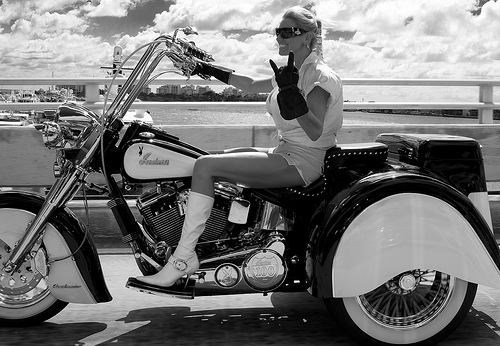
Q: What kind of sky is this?
A: Cloudy sky.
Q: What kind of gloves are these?
A: Black gloves.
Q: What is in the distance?
A: A body of water.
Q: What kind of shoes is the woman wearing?
A: Boots.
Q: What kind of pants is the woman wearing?
A: Shorts.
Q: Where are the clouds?
A: In sky.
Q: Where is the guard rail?
A: Behind bike.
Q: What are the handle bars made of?
A: Chrome.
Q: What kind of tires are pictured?
A: White wall.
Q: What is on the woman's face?
A: Sun Glasses.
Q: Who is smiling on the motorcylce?
A: A girl with a white shirt and boots.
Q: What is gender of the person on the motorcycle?
A: A female.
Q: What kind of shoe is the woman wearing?
A: White knee high boots.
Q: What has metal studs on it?
A: The black leather seat.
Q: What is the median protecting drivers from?
A: Water.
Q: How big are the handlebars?
A: Long.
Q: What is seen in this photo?
A: A wheel.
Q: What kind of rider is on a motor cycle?
A: A lady rider.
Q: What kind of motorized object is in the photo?
A: A motor cycle.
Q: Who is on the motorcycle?
A: A woman.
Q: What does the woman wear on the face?
A: Sunglasses.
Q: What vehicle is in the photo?
A: A motorcycle.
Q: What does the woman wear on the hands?
A: Gloves.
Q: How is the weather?
A: Warm.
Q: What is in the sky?
A: Clouds.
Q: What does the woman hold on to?
A: The handlebars.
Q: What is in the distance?
A: A city skyline.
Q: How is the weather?
A: Partly cloudy.